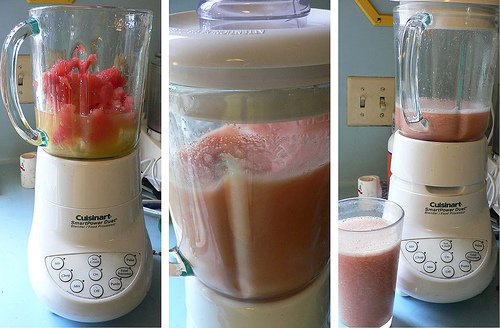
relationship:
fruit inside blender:
[35, 45, 141, 157] [0, 2, 162, 328]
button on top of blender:
[85, 251, 103, 269] [0, 2, 162, 328]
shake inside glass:
[337, 215, 404, 327] [338, 193, 409, 328]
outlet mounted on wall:
[345, 74, 400, 135] [337, 1, 409, 203]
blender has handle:
[0, 2, 162, 328] [0, 15, 54, 155]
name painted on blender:
[65, 209, 123, 234] [0, 2, 162, 328]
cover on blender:
[164, 0, 332, 87] [166, 0, 332, 328]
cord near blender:
[138, 153, 168, 216] [0, 2, 162, 328]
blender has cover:
[166, 0, 332, 328] [164, 0, 332, 87]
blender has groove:
[166, 0, 332, 328] [195, 149, 269, 302]